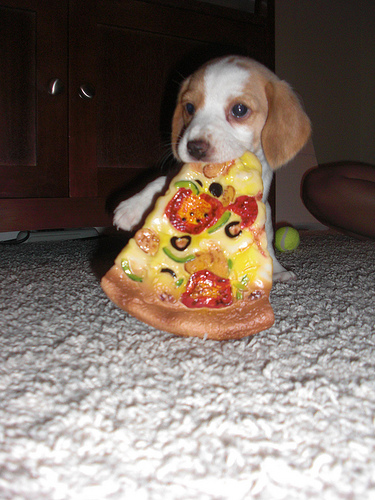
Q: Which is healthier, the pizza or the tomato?
A: The tomato is healthier than the pizza.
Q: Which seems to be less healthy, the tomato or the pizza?
A: The pizza is less healthy than the tomato.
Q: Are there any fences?
A: No, there are no fences.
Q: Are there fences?
A: No, there are no fences.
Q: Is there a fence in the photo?
A: No, there are no fences.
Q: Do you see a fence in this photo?
A: No, there are no fences.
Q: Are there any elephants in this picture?
A: No, there are no elephants.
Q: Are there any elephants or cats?
A: No, there are no elephants or cats.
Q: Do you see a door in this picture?
A: Yes, there is a door.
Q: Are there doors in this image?
A: Yes, there is a door.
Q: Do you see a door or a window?
A: Yes, there is a door.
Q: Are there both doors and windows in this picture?
A: No, there is a door but no windows.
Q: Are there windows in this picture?
A: No, there are no windows.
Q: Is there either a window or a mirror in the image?
A: No, there are no windows or mirrors.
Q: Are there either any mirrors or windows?
A: No, there are no windows or mirrors.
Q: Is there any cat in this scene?
A: No, there are no cats.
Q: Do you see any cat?
A: No, there are no cats.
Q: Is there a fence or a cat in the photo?
A: No, there are no cats or fences.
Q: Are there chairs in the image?
A: No, there are no chairs.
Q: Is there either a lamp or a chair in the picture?
A: No, there are no chairs or lamps.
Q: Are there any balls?
A: Yes, there is a ball.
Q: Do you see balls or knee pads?
A: Yes, there is a ball.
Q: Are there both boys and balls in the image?
A: No, there is a ball but no boys.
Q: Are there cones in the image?
A: No, there are no cones.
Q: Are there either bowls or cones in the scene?
A: No, there are no cones or bowls.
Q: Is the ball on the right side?
A: Yes, the ball is on the right of the image.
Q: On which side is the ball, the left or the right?
A: The ball is on the right of the image.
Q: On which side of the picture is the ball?
A: The ball is on the right of the image.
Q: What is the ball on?
A: The ball is on the carpet.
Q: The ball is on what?
A: The ball is on the carpet.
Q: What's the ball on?
A: The ball is on the carpet.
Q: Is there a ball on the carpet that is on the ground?
A: Yes, there is a ball on the carpet.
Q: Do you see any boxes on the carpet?
A: No, there is a ball on the carpet.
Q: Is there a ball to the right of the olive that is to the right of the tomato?
A: Yes, there is a ball to the right of the olive.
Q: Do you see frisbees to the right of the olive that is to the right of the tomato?
A: No, there is a ball to the right of the olive.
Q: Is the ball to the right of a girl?
A: No, the ball is to the right of an olive.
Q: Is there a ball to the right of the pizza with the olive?
A: Yes, there is a ball to the right of the pizza.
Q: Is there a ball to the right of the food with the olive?
A: Yes, there is a ball to the right of the pizza.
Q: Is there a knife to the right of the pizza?
A: No, there is a ball to the right of the pizza.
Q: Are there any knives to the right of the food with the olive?
A: No, there is a ball to the right of the pizza.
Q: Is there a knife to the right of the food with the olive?
A: No, there is a ball to the right of the pizza.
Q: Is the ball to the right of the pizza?
A: Yes, the ball is to the right of the pizza.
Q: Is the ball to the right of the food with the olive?
A: Yes, the ball is to the right of the pizza.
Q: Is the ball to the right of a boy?
A: No, the ball is to the right of the pizza.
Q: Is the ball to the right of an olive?
A: Yes, the ball is to the right of an olive.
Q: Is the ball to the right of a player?
A: No, the ball is to the right of an olive.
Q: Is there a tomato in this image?
A: Yes, there is a tomato.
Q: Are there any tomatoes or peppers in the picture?
A: Yes, there is a tomato.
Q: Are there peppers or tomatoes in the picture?
A: Yes, there is a tomato.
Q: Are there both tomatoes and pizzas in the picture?
A: Yes, there are both a tomato and a pizza.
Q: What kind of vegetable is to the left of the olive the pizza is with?
A: The vegetable is a tomato.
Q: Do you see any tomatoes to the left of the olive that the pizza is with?
A: Yes, there is a tomato to the left of the olive.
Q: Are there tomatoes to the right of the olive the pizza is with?
A: No, the tomato is to the left of the olive.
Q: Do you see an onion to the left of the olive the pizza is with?
A: No, there is a tomato to the left of the olive.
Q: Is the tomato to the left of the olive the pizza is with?
A: Yes, the tomato is to the left of the olive.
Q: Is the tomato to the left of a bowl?
A: No, the tomato is to the left of the olive.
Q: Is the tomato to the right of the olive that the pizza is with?
A: No, the tomato is to the left of the olive.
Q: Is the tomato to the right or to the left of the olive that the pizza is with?
A: The tomato is to the left of the olive.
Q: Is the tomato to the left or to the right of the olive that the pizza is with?
A: The tomato is to the left of the olive.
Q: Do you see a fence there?
A: No, there are no fences.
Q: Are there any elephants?
A: No, there are no elephants.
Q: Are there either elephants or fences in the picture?
A: No, there are no elephants or fences.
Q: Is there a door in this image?
A: Yes, there is a door.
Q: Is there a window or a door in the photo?
A: Yes, there is a door.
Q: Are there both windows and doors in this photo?
A: No, there is a door but no windows.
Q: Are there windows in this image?
A: No, there are no windows.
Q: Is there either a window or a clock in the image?
A: No, there are no windows or clocks.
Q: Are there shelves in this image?
A: No, there are no shelves.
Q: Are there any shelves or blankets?
A: No, there are no shelves or blankets.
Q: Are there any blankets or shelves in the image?
A: No, there are no shelves or blankets.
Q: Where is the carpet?
A: The carpet is on the ground.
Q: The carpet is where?
A: The carpet is on the ground.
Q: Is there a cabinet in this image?
A: Yes, there is a cabinet.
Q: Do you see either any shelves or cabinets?
A: Yes, there is a cabinet.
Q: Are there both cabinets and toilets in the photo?
A: No, there is a cabinet but no toilets.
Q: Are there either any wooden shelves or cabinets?
A: Yes, there is a wood cabinet.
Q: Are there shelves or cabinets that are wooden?
A: Yes, the cabinet is wooden.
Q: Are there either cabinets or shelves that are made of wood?
A: Yes, the cabinet is made of wood.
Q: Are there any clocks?
A: No, there are no clocks.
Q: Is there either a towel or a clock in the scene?
A: No, there are no clocks or towels.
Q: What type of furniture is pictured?
A: The furniture is a cabinet.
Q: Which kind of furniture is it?
A: The piece of furniture is a cabinet.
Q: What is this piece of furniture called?
A: This is a cabinet.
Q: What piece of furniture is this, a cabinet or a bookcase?
A: This is a cabinet.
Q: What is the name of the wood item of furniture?
A: The piece of furniture is a cabinet.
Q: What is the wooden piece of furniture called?
A: The piece of furniture is a cabinet.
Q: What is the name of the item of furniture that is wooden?
A: The piece of furniture is a cabinet.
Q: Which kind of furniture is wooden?
A: The furniture is a cabinet.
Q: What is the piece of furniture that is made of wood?
A: The piece of furniture is a cabinet.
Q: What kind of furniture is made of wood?
A: The furniture is a cabinet.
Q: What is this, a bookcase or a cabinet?
A: This is a cabinet.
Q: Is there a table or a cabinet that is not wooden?
A: No, there is a cabinet but it is wooden.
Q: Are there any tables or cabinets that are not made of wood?
A: No, there is a cabinet but it is made of wood.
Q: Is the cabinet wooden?
A: Yes, the cabinet is wooden.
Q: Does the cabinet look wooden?
A: Yes, the cabinet is wooden.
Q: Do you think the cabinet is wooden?
A: Yes, the cabinet is wooden.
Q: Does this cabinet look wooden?
A: Yes, the cabinet is wooden.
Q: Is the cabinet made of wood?
A: Yes, the cabinet is made of wood.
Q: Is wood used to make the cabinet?
A: Yes, the cabinet is made of wood.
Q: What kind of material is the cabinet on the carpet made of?
A: The cabinet is made of wood.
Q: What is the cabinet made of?
A: The cabinet is made of wood.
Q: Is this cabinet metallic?
A: No, the cabinet is wooden.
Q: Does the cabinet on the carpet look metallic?
A: No, the cabinet is wooden.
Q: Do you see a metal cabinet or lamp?
A: No, there is a cabinet but it is wooden.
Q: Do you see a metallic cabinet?
A: No, there is a cabinet but it is wooden.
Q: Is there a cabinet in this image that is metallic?
A: No, there is a cabinet but it is wooden.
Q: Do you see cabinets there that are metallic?
A: No, there is a cabinet but it is wooden.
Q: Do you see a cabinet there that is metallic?
A: No, there is a cabinet but it is wooden.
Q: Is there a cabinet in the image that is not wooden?
A: No, there is a cabinet but it is wooden.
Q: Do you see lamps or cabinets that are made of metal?
A: No, there is a cabinet but it is made of wood.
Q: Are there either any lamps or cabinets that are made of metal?
A: No, there is a cabinet but it is made of wood.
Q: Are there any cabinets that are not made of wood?
A: No, there is a cabinet but it is made of wood.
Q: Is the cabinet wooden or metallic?
A: The cabinet is wooden.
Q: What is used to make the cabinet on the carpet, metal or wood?
A: The cabinet is made of wood.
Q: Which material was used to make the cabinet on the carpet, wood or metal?
A: The cabinet is made of wood.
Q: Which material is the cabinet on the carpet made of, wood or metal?
A: The cabinet is made of wood.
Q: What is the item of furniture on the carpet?
A: The piece of furniture is a cabinet.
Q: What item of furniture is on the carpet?
A: The piece of furniture is a cabinet.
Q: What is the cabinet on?
A: The cabinet is on the carpet.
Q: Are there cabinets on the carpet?
A: Yes, there is a cabinet on the carpet.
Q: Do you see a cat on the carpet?
A: No, there is a cabinet on the carpet.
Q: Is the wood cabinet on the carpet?
A: Yes, the cabinet is on the carpet.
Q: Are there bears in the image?
A: No, there are no bears.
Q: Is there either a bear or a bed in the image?
A: No, there are no bears or beds.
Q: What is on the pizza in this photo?
A: The olive is on the pizza.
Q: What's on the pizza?
A: The olive is on the pizza.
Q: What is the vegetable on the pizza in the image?
A: The vegetable is an olive.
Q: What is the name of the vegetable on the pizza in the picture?
A: The vegetable is an olive.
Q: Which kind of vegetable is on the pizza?
A: The vegetable is an olive.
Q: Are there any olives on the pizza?
A: Yes, there is an olive on the pizza.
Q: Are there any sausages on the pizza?
A: No, there is an olive on the pizza.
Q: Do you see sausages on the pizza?
A: No, there is an olive on the pizza.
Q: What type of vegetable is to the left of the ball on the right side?
A: The vegetable is an olive.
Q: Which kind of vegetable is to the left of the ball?
A: The vegetable is an olive.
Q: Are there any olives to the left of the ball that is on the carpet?
A: Yes, there is an olive to the left of the ball.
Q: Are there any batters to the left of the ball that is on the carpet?
A: No, there is an olive to the left of the ball.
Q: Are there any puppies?
A: Yes, there is a puppy.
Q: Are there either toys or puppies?
A: Yes, there is a puppy.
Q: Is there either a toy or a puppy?
A: Yes, there is a puppy.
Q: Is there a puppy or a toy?
A: Yes, there is a puppy.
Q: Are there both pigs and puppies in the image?
A: No, there is a puppy but no pigs.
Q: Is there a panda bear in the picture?
A: No, there are no panda bears.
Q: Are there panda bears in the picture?
A: No, there are no panda bears.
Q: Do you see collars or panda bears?
A: No, there are no panda bears or collars.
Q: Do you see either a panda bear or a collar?
A: No, there are no panda bears or collars.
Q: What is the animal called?
A: The animal is a puppy.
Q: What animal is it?
A: The animal is a puppy.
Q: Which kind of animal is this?
A: This is a puppy.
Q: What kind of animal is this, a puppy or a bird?
A: This is a puppy.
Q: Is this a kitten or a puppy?
A: This is a puppy.